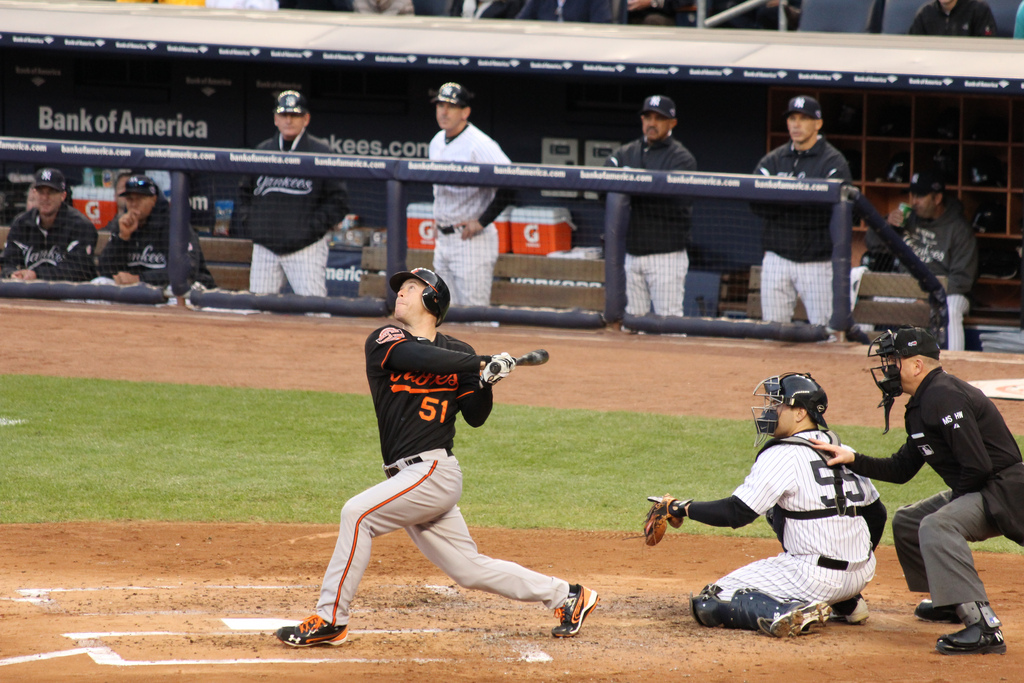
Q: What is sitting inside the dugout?
A: The cooler is sitting inside the dugout.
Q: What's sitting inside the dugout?
A: The cooler is sitting inside the dugout.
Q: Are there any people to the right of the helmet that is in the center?
A: Yes, there is a person to the right of the helmet.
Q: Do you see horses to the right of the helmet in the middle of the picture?
A: No, there is a person to the right of the helmet.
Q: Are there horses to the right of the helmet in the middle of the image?
A: No, there is a person to the right of the helmet.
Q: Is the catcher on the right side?
A: Yes, the catcher is on the right of the image.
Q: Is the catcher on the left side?
A: No, the catcher is on the right of the image.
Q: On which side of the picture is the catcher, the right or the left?
A: The catcher is on the right of the image.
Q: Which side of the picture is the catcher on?
A: The catcher is on the right of the image.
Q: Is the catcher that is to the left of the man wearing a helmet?
A: Yes, the catcher is wearing a helmet.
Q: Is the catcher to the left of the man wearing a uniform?
A: No, the catcher is wearing a helmet.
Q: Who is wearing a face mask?
A: The catcher is wearing a face mask.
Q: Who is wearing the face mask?
A: The catcher is wearing a face mask.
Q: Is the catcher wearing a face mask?
A: Yes, the catcher is wearing a face mask.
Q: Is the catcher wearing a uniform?
A: No, the catcher is wearing a face mask.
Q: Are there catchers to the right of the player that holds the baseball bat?
A: Yes, there is a catcher to the right of the player.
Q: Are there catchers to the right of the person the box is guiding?
A: Yes, there is a catcher to the right of the player.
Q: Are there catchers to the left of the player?
A: No, the catcher is to the right of the player.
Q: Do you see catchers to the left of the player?
A: No, the catcher is to the right of the player.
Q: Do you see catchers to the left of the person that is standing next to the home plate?
A: No, the catcher is to the right of the player.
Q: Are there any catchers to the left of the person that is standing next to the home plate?
A: No, the catcher is to the right of the player.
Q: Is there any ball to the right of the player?
A: No, there is a catcher to the right of the player.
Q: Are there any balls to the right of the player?
A: No, there is a catcher to the right of the player.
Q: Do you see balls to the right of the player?
A: No, there is a catcher to the right of the player.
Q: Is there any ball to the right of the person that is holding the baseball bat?
A: No, there is a catcher to the right of the player.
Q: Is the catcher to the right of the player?
A: Yes, the catcher is to the right of the player.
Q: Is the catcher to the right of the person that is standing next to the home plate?
A: Yes, the catcher is to the right of the player.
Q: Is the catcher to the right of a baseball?
A: No, the catcher is to the right of the player.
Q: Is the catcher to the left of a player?
A: No, the catcher is to the right of a player.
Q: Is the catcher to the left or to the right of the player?
A: The catcher is to the right of the player.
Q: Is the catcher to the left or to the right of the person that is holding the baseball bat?
A: The catcher is to the right of the player.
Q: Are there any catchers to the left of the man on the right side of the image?
A: Yes, there is a catcher to the left of the man.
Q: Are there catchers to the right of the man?
A: No, the catcher is to the left of the man.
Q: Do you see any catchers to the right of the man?
A: No, the catcher is to the left of the man.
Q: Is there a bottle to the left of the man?
A: No, there is a catcher to the left of the man.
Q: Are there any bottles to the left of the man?
A: No, there is a catcher to the left of the man.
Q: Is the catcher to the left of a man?
A: Yes, the catcher is to the left of a man.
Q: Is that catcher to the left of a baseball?
A: No, the catcher is to the left of a man.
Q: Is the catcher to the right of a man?
A: No, the catcher is to the left of a man.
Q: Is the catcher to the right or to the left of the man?
A: The catcher is to the left of the man.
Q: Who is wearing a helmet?
A: The catcher is wearing a helmet.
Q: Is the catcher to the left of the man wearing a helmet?
A: Yes, the catcher is wearing a helmet.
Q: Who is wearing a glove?
A: The catcher is wearing a glove.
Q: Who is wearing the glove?
A: The catcher is wearing a glove.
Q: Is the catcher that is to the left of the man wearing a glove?
A: Yes, the catcher is wearing a glove.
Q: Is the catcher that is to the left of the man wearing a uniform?
A: No, the catcher is wearing a glove.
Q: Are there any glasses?
A: No, there are no glasses.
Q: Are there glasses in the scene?
A: No, there are no glasses.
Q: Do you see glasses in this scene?
A: No, there are no glasses.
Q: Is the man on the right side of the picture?
A: Yes, the man is on the right of the image.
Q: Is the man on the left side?
A: No, the man is on the right of the image.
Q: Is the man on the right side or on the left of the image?
A: The man is on the right of the image.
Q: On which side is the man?
A: The man is on the right of the image.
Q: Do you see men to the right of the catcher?
A: Yes, there is a man to the right of the catcher.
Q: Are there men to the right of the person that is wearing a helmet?
A: Yes, there is a man to the right of the catcher.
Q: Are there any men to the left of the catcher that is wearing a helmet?
A: No, the man is to the right of the catcher.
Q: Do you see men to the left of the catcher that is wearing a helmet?
A: No, the man is to the right of the catcher.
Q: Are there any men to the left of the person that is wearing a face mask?
A: No, the man is to the right of the catcher.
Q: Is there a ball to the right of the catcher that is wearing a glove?
A: No, there is a man to the right of the catcher.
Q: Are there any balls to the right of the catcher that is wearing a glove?
A: No, there is a man to the right of the catcher.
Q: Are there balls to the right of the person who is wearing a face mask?
A: No, there is a man to the right of the catcher.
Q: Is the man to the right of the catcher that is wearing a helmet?
A: Yes, the man is to the right of the catcher.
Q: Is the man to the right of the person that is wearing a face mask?
A: Yes, the man is to the right of the catcher.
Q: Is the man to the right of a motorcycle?
A: No, the man is to the right of the catcher.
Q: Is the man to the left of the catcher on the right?
A: No, the man is to the right of the catcher.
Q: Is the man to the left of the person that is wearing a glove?
A: No, the man is to the right of the catcher.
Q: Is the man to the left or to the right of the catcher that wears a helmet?
A: The man is to the right of the catcher.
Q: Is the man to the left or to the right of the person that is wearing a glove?
A: The man is to the right of the catcher.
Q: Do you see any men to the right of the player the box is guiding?
A: Yes, there is a man to the right of the player.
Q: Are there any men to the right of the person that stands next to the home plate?
A: Yes, there is a man to the right of the player.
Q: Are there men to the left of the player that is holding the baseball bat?
A: No, the man is to the right of the player.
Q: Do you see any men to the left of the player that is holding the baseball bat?
A: No, the man is to the right of the player.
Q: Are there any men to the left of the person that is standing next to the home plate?
A: No, the man is to the right of the player.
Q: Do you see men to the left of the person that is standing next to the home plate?
A: No, the man is to the right of the player.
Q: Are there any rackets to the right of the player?
A: No, there is a man to the right of the player.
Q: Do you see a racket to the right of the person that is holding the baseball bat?
A: No, there is a man to the right of the player.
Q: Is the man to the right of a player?
A: Yes, the man is to the right of a player.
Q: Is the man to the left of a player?
A: No, the man is to the right of a player.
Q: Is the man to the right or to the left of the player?
A: The man is to the right of the player.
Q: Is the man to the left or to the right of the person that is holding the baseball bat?
A: The man is to the right of the player.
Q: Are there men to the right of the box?
A: Yes, there is a man to the right of the box.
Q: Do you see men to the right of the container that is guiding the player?
A: Yes, there is a man to the right of the box.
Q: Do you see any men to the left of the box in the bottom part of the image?
A: No, the man is to the right of the box.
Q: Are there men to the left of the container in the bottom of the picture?
A: No, the man is to the right of the box.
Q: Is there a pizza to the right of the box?
A: No, there is a man to the right of the box.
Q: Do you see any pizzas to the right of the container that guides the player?
A: No, there is a man to the right of the box.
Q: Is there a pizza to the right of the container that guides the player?
A: No, there is a man to the right of the box.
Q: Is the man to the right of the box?
A: Yes, the man is to the right of the box.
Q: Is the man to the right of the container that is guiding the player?
A: Yes, the man is to the right of the box.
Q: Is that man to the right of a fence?
A: No, the man is to the right of the box.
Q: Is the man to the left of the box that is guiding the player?
A: No, the man is to the right of the box.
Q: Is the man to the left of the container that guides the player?
A: No, the man is to the right of the box.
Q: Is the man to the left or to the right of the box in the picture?
A: The man is to the right of the box.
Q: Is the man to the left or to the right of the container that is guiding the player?
A: The man is to the right of the box.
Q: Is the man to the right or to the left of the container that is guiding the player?
A: The man is to the right of the box.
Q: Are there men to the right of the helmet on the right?
A: Yes, there is a man to the right of the helmet.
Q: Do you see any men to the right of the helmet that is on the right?
A: Yes, there is a man to the right of the helmet.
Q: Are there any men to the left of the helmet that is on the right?
A: No, the man is to the right of the helmet.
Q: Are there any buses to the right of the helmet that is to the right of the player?
A: No, there is a man to the right of the helmet.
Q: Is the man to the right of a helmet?
A: Yes, the man is to the right of a helmet.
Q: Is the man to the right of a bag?
A: No, the man is to the right of a helmet.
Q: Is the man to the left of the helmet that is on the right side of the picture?
A: No, the man is to the right of the helmet.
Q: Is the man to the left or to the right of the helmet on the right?
A: The man is to the right of the helmet.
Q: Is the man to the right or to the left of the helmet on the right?
A: The man is to the right of the helmet.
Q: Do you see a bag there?
A: No, there are no bags.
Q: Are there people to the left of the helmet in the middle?
A: Yes, there is a person to the left of the helmet.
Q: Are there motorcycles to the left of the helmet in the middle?
A: No, there is a person to the left of the helmet.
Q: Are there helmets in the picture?
A: Yes, there is a helmet.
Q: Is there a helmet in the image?
A: Yes, there is a helmet.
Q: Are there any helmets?
A: Yes, there is a helmet.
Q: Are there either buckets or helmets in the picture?
A: Yes, there is a helmet.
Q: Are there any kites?
A: No, there are no kites.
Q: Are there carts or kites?
A: No, there are no kites or carts.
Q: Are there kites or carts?
A: No, there are no kites or carts.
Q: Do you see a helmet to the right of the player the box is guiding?
A: Yes, there is a helmet to the right of the player.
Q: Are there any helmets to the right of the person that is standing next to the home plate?
A: Yes, there is a helmet to the right of the player.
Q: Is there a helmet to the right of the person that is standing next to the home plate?
A: Yes, there is a helmet to the right of the player.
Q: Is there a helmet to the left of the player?
A: No, the helmet is to the right of the player.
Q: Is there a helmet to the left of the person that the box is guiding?
A: No, the helmet is to the right of the player.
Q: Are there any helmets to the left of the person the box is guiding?
A: No, the helmet is to the right of the player.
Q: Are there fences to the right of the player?
A: No, there is a helmet to the right of the player.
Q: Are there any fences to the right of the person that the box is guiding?
A: No, there is a helmet to the right of the player.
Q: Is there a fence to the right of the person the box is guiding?
A: No, there is a helmet to the right of the player.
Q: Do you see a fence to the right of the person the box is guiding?
A: No, there is a helmet to the right of the player.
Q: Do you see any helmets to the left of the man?
A: Yes, there is a helmet to the left of the man.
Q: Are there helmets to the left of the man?
A: Yes, there is a helmet to the left of the man.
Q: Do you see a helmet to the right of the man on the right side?
A: No, the helmet is to the left of the man.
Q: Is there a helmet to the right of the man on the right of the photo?
A: No, the helmet is to the left of the man.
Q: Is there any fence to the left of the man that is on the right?
A: No, there is a helmet to the left of the man.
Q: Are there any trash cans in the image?
A: No, there are no trash cans.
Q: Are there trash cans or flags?
A: No, there are no trash cans or flags.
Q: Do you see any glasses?
A: No, there are no glasses.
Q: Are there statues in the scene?
A: No, there are no statues.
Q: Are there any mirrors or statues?
A: No, there are no statues or mirrors.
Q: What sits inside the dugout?
A: The cooler sits inside the dugout.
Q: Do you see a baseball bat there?
A: Yes, there is a baseball bat.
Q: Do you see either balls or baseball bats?
A: Yes, there is a baseball bat.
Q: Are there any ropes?
A: No, there are no ropes.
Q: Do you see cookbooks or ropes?
A: No, there are no ropes or cookbooks.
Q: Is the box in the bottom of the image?
A: Yes, the box is in the bottom of the image.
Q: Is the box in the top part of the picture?
A: No, the box is in the bottom of the image.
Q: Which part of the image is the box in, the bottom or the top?
A: The box is in the bottom of the image.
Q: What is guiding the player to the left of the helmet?
A: The box is guiding the player.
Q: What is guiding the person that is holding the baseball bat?
A: The box is guiding the player.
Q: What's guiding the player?
A: The box is guiding the player.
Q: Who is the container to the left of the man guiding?
A: The box is guiding the player.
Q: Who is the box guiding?
A: The box is guiding the player.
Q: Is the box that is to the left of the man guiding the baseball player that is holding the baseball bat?
A: Yes, the box is guiding the player.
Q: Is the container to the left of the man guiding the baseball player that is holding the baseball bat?
A: Yes, the box is guiding the player.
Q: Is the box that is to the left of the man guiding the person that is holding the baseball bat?
A: Yes, the box is guiding the player.